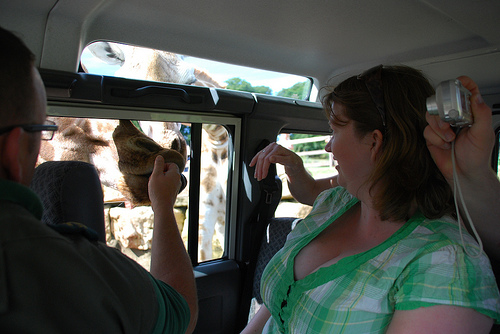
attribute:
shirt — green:
[233, 167, 483, 332]